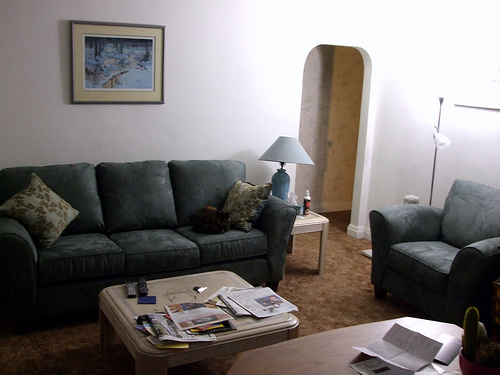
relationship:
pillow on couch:
[4, 170, 81, 254] [0, 150, 305, 335]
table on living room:
[98, 267, 299, 372] [3, 6, 488, 368]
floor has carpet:
[2, 232, 365, 372] [282, 232, 372, 328]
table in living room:
[98, 267, 299, 372] [3, 6, 488, 368]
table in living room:
[288, 202, 333, 275] [3, 6, 488, 368]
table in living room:
[218, 315, 478, 373] [3, 6, 488, 368]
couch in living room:
[0, 150, 305, 335] [3, 6, 488, 368]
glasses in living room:
[166, 288, 197, 301] [0, 0, 500, 375]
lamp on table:
[257, 135, 313, 199] [285, 210, 330, 276]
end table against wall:
[281, 202, 328, 277] [1, 1, 389, 236]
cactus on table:
[462, 307, 487, 361] [224, 313, 499, 370]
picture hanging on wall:
[61, 16, 168, 108] [2, 6, 498, 249]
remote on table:
[137, 280, 149, 296] [98, 267, 299, 372]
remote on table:
[126, 278, 136, 295] [98, 267, 299, 372]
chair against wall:
[360, 179, 499, 313] [446, 109, 495, 181]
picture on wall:
[70, 20, 166, 105] [2, 6, 498, 249]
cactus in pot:
[465, 307, 487, 355] [456, 351, 483, 371]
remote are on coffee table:
[125, 280, 137, 298] [92, 267, 303, 374]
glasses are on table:
[162, 285, 197, 300] [98, 267, 299, 372]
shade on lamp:
[258, 136, 313, 164] [257, 135, 313, 199]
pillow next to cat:
[221, 180, 273, 233] [189, 205, 231, 235]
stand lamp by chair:
[416, 92, 450, 202] [360, 179, 499, 313]